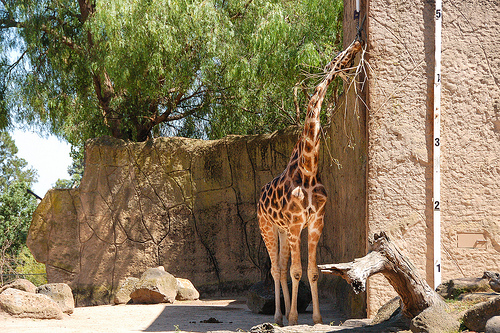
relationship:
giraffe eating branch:
[250, 35, 374, 328] [290, 44, 377, 150]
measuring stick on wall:
[433, 2, 443, 330] [330, 0, 499, 331]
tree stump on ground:
[316, 229, 499, 330] [10, 286, 498, 331]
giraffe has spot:
[250, 35, 374, 328] [300, 154, 314, 171]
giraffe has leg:
[250, 35, 374, 328] [281, 223, 307, 331]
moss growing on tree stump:
[436, 286, 472, 307] [316, 229, 499, 330]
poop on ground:
[188, 314, 232, 325] [10, 286, 498, 331]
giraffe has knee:
[250, 35, 374, 328] [291, 267, 303, 279]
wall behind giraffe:
[30, 119, 330, 302] [250, 35, 374, 328]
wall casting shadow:
[330, 0, 499, 331] [147, 301, 353, 328]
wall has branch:
[330, 0, 499, 331] [290, 44, 377, 150]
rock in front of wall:
[131, 264, 182, 301] [30, 119, 330, 302]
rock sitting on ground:
[131, 264, 182, 301] [10, 286, 498, 331]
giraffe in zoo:
[250, 35, 374, 328] [5, 1, 500, 330]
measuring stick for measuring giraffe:
[433, 2, 443, 330] [250, 35, 374, 328]